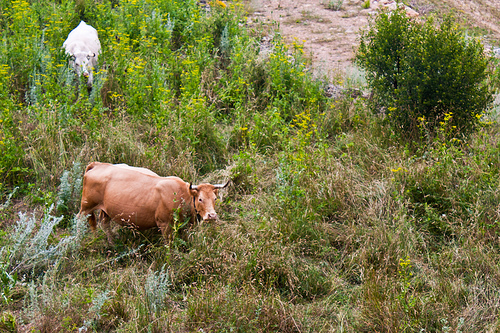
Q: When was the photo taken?
A: Daytime.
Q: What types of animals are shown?
A: Cows.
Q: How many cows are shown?
A: Two.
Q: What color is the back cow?
A: White.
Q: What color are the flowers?
A: Yellow.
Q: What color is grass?
A: Brown.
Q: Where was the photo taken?
A: In a grassy knoll.